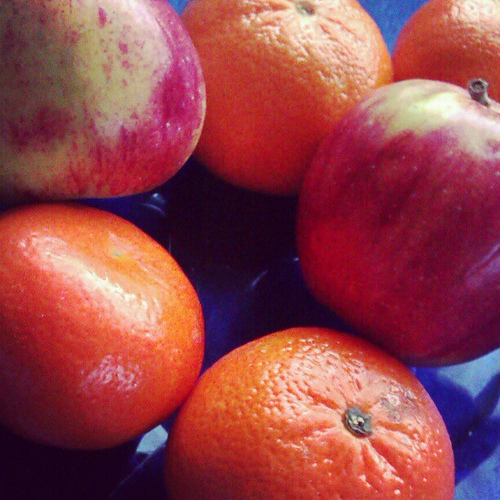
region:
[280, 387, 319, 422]
small dimple on orange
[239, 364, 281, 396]
small dimple on orange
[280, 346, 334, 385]
small dimple on orange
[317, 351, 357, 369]
small dimple on orange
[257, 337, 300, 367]
small dimple on orange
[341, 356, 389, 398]
small dimple on orange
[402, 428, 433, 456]
small dimple on orange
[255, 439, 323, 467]
small dimple on orange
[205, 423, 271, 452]
small dimple on orange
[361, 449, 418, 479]
small dimple on orange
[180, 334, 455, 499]
Ripe orange on blue cloth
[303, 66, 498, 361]
Large red apple with green spot on top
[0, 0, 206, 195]
Yellow and red apple on blue cloth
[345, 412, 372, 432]
Center pit of ripe orange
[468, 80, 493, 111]
Brown stem on top of red apple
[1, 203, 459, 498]
Two ripe oranges next to each other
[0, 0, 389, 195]
Ripe orange beside yellow and red apple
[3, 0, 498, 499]
Apples and oranges arranged on blue cloth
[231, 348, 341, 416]
Several pitted marks on ripe orange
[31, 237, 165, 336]
Light reflecting off orange's surface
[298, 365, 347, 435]
part pf a peel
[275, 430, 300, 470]
par tof a line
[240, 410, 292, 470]
par tof a peel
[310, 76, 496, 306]
an apple in a pile of fruit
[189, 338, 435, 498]
an orange in a pile of fruit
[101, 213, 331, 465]
fruit on a blue cloth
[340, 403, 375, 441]
navel of an orange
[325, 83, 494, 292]
the apple is light red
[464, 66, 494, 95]
the stem of an apple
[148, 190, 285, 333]
a blue cloth is under the fruit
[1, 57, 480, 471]
apples and oranges on the table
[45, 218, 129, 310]
light reflecting off an orange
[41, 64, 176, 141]
apple is yellow and red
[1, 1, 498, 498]
fruit on glass plate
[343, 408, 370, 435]
orange has brown navel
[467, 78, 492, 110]
apple has dark brown stem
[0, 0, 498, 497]
the glass is blue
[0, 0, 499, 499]
the oranges are orange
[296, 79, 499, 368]
apple is red small patch of yellow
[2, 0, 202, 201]
apple is red and yellow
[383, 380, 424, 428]
bruising on orange near navel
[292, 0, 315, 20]
orange has navel missing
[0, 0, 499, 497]
fruit reflects light source